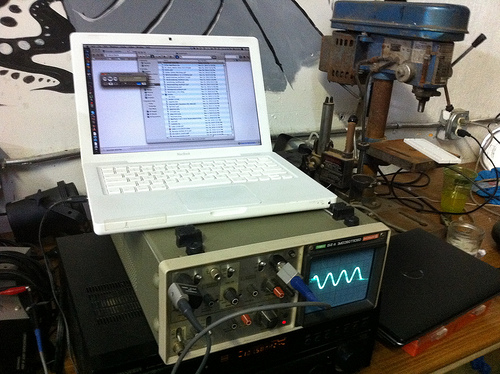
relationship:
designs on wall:
[0, 0, 77, 95] [6, 4, 347, 137]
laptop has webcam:
[70, 30, 339, 234] [158, 32, 193, 48]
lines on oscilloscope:
[312, 265, 367, 293] [308, 250, 381, 325]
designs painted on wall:
[7, 7, 305, 79] [6, 4, 347, 137]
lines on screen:
[312, 265, 367, 293] [303, 255, 377, 310]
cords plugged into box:
[454, 113, 499, 188] [437, 103, 460, 143]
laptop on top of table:
[373, 206, 499, 335] [0, 160, 499, 374]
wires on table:
[354, 159, 466, 225] [0, 160, 499, 374]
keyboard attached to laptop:
[97, 158, 297, 196] [51, 26, 346, 234]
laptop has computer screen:
[51, 26, 346, 234] [82, 46, 266, 145]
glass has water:
[442, 156, 482, 221] [440, 196, 469, 213]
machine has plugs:
[332, 7, 487, 58] [351, 167, 453, 212]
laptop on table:
[373, 206, 499, 335] [357, 174, 493, 297]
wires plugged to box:
[354, 159, 466, 225] [437, 103, 460, 143]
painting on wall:
[11, 6, 332, 90] [6, 4, 347, 137]